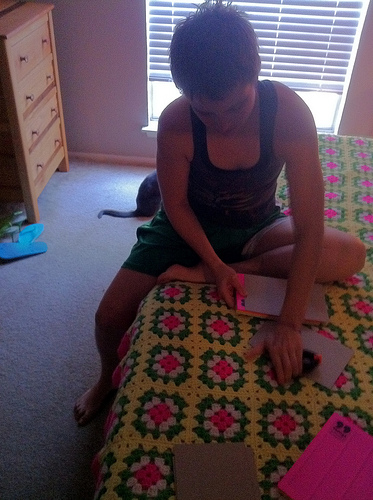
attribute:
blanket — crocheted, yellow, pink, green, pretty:
[89, 125, 370, 499]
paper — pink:
[274, 408, 371, 499]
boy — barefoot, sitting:
[71, 1, 366, 429]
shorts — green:
[121, 206, 288, 277]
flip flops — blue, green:
[1, 219, 49, 263]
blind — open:
[147, 3, 363, 95]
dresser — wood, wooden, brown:
[1, 3, 73, 226]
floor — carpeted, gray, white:
[2, 159, 164, 498]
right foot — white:
[70, 376, 119, 429]